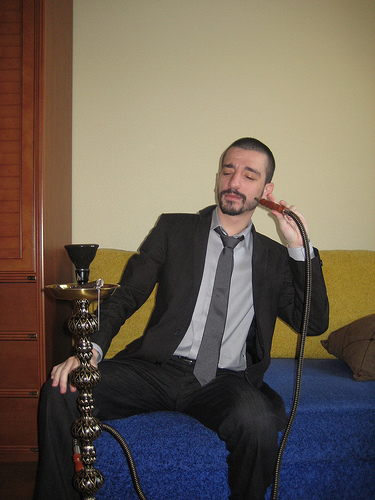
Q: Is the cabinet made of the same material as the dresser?
A: Yes, both the cabinet and the dresser are made of wood.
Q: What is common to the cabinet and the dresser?
A: The material, both the cabinet and the dresser are wooden.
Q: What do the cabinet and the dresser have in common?
A: The material, both the cabinet and the dresser are wooden.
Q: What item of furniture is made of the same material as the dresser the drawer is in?
A: The cabinet is made of the same material as the dresser.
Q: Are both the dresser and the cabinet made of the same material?
A: Yes, both the dresser and the cabinet are made of wood.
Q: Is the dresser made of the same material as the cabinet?
A: Yes, both the dresser and the cabinet are made of wood.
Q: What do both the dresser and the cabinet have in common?
A: The material, both the dresser and the cabinet are wooden.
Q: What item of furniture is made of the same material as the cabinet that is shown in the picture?
A: The dresser is made of the same material as the cabinet.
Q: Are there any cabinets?
A: Yes, there is a cabinet.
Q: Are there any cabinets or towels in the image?
A: Yes, there is a cabinet.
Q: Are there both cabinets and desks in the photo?
A: No, there is a cabinet but no desks.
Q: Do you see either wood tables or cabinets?
A: Yes, there is a wood cabinet.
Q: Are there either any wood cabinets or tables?
A: Yes, there is a wood cabinet.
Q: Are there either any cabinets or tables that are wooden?
A: Yes, the cabinet is wooden.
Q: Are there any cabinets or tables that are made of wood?
A: Yes, the cabinet is made of wood.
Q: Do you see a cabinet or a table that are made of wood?
A: Yes, the cabinet is made of wood.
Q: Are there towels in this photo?
A: No, there are no towels.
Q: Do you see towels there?
A: No, there are no towels.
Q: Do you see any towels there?
A: No, there are no towels.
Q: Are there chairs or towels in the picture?
A: No, there are no towels or chairs.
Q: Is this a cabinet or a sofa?
A: This is a cabinet.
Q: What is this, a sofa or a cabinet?
A: This is a cabinet.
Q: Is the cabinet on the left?
A: Yes, the cabinet is on the left of the image.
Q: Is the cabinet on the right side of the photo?
A: No, the cabinet is on the left of the image.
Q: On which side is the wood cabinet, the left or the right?
A: The cabinet is on the left of the image.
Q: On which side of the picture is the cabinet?
A: The cabinet is on the left of the image.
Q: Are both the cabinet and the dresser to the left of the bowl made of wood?
A: Yes, both the cabinet and the dresser are made of wood.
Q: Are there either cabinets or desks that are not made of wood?
A: No, there is a cabinet but it is made of wood.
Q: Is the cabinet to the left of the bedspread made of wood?
A: Yes, the cabinet is made of wood.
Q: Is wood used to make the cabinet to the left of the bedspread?
A: Yes, the cabinet is made of wood.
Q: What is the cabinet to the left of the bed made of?
A: The cabinet is made of wood.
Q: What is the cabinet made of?
A: The cabinet is made of wood.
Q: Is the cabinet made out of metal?
A: No, the cabinet is made of wood.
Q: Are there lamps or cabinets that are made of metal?
A: No, there is a cabinet but it is made of wood.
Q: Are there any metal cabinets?
A: No, there is a cabinet but it is made of wood.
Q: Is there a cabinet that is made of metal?
A: No, there is a cabinet but it is made of wood.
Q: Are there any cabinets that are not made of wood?
A: No, there is a cabinet but it is made of wood.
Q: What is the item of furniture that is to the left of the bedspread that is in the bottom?
A: The piece of furniture is a cabinet.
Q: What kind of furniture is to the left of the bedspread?
A: The piece of furniture is a cabinet.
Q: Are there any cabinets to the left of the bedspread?
A: Yes, there is a cabinet to the left of the bedspread.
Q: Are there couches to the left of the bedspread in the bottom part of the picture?
A: No, there is a cabinet to the left of the bedspread.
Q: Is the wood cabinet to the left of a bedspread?
A: Yes, the cabinet is to the left of a bedspread.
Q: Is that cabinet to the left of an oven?
A: No, the cabinet is to the left of a bedspread.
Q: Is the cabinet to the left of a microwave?
A: No, the cabinet is to the left of the pillow.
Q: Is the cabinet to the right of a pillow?
A: No, the cabinet is to the left of a pillow.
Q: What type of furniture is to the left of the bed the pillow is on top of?
A: The piece of furniture is a cabinet.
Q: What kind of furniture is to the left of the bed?
A: The piece of furniture is a cabinet.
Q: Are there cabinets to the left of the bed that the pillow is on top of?
A: Yes, there is a cabinet to the left of the bed.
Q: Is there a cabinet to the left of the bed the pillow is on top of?
A: Yes, there is a cabinet to the left of the bed.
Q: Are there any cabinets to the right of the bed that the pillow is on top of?
A: No, the cabinet is to the left of the bed.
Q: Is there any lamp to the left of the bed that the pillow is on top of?
A: No, there is a cabinet to the left of the bed.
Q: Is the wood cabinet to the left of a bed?
A: Yes, the cabinet is to the left of a bed.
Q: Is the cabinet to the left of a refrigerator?
A: No, the cabinet is to the left of a bed.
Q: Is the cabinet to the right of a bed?
A: No, the cabinet is to the left of a bed.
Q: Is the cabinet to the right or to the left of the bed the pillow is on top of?
A: The cabinet is to the left of the bed.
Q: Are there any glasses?
A: No, there are no glasses.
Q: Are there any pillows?
A: Yes, there is a pillow.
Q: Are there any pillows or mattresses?
A: Yes, there is a pillow.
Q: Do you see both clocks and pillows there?
A: No, there is a pillow but no clocks.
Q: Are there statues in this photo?
A: No, there are no statues.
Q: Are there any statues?
A: No, there are no statues.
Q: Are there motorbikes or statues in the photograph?
A: No, there are no statues or motorbikes.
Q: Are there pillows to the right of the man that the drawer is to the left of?
A: Yes, there is a pillow to the right of the man.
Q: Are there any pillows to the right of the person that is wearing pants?
A: Yes, there is a pillow to the right of the man.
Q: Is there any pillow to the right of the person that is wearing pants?
A: Yes, there is a pillow to the right of the man.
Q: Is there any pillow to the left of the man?
A: No, the pillow is to the right of the man.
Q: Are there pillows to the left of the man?
A: No, the pillow is to the right of the man.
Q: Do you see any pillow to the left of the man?
A: No, the pillow is to the right of the man.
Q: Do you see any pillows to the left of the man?
A: No, the pillow is to the right of the man.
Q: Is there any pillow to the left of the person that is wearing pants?
A: No, the pillow is to the right of the man.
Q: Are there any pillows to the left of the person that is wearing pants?
A: No, the pillow is to the right of the man.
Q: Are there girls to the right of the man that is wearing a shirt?
A: No, there is a pillow to the right of the man.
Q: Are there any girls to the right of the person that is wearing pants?
A: No, there is a pillow to the right of the man.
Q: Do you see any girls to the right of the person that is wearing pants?
A: No, there is a pillow to the right of the man.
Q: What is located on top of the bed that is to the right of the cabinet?
A: The pillow is on top of the bed.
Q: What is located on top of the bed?
A: The pillow is on top of the bed.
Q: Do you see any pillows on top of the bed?
A: Yes, there is a pillow on top of the bed.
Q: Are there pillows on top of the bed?
A: Yes, there is a pillow on top of the bed.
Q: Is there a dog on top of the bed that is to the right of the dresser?
A: No, there is a pillow on top of the bed.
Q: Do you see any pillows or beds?
A: Yes, there is a pillow.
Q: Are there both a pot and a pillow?
A: No, there is a pillow but no pots.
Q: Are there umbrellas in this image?
A: No, there are no umbrellas.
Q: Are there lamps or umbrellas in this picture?
A: No, there are no umbrellas or lamps.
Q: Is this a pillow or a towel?
A: This is a pillow.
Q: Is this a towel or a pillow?
A: This is a pillow.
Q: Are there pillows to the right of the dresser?
A: Yes, there is a pillow to the right of the dresser.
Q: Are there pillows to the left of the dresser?
A: No, the pillow is to the right of the dresser.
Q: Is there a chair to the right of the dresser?
A: No, there is a pillow to the right of the dresser.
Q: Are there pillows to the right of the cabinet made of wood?
A: Yes, there is a pillow to the right of the cabinet.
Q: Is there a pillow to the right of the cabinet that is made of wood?
A: Yes, there is a pillow to the right of the cabinet.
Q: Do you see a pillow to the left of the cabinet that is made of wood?
A: No, the pillow is to the right of the cabinet.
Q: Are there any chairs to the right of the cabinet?
A: No, there is a pillow to the right of the cabinet.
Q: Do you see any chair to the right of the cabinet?
A: No, there is a pillow to the right of the cabinet.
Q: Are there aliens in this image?
A: No, there are no aliens.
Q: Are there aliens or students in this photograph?
A: No, there are no aliens or students.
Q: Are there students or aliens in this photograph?
A: No, there are no aliens or students.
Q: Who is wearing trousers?
A: The man is wearing trousers.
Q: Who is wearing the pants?
A: The man is wearing trousers.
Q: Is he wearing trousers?
A: Yes, the man is wearing trousers.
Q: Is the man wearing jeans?
A: No, the man is wearing trousers.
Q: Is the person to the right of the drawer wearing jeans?
A: No, the man is wearing trousers.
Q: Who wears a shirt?
A: The man wears a shirt.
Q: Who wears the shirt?
A: The man wears a shirt.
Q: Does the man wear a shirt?
A: Yes, the man wears a shirt.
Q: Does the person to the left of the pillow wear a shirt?
A: Yes, the man wears a shirt.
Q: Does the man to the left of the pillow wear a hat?
A: No, the man wears a shirt.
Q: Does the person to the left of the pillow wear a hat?
A: No, the man wears a shirt.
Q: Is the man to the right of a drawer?
A: Yes, the man is to the right of a drawer.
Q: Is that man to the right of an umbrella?
A: No, the man is to the right of a drawer.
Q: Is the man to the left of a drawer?
A: No, the man is to the right of a drawer.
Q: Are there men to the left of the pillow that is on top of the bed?
A: Yes, there is a man to the left of the pillow.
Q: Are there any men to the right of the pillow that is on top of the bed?
A: No, the man is to the left of the pillow.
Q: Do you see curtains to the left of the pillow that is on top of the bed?
A: No, there is a man to the left of the pillow.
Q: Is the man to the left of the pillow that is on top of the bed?
A: Yes, the man is to the left of the pillow.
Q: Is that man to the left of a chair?
A: No, the man is to the left of the pillow.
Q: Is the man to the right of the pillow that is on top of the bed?
A: No, the man is to the left of the pillow.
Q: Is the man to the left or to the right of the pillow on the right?
A: The man is to the left of the pillow.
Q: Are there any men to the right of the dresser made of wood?
A: Yes, there is a man to the right of the dresser.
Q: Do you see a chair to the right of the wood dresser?
A: No, there is a man to the right of the dresser.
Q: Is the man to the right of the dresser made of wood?
A: Yes, the man is to the right of the dresser.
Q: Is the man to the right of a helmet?
A: No, the man is to the right of the dresser.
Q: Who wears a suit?
A: The man wears a suit.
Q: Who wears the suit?
A: The man wears a suit.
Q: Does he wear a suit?
A: Yes, the man wears a suit.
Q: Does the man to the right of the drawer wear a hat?
A: No, the man wears a suit.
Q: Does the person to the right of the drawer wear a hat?
A: No, the man wears a suit.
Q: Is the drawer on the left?
A: Yes, the drawer is on the left of the image.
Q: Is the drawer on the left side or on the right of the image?
A: The drawer is on the left of the image.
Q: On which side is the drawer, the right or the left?
A: The drawer is on the left of the image.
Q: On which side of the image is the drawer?
A: The drawer is on the left of the image.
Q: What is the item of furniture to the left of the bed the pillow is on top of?
A: The piece of furniture is a drawer.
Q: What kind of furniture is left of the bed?
A: The piece of furniture is a drawer.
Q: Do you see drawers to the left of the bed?
A: Yes, there is a drawer to the left of the bed.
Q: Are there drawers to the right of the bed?
A: No, the drawer is to the left of the bed.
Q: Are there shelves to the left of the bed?
A: No, there is a drawer to the left of the bed.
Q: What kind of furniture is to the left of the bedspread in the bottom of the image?
A: The piece of furniture is a drawer.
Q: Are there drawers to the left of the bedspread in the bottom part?
A: Yes, there is a drawer to the left of the bedspread.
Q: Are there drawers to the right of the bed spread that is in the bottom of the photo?
A: No, the drawer is to the left of the bedspread.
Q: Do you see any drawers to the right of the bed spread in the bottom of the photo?
A: No, the drawer is to the left of the bedspread.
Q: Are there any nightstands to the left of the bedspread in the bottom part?
A: No, there is a drawer to the left of the bedspread.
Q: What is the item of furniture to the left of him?
A: The piece of furniture is a drawer.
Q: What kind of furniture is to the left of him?
A: The piece of furniture is a drawer.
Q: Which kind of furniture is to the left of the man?
A: The piece of furniture is a drawer.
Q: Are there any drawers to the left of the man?
A: Yes, there is a drawer to the left of the man.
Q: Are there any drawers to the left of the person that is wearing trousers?
A: Yes, there is a drawer to the left of the man.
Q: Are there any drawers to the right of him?
A: No, the drawer is to the left of the man.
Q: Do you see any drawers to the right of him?
A: No, the drawer is to the left of the man.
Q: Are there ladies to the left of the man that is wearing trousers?
A: No, there is a drawer to the left of the man.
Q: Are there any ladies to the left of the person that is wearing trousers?
A: No, there is a drawer to the left of the man.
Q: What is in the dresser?
A: The drawer is in the dresser.